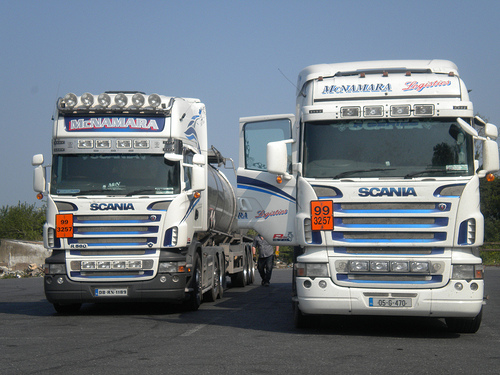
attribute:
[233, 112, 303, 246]
truck door — OPEN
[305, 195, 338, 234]
sign — red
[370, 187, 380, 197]
letter — blue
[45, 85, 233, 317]
truck —  left 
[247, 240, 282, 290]
man — walking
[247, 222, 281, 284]
man — walking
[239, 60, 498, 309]
truck — large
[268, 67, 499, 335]
truck — large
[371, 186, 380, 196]
letter — blue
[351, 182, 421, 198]
letter — blue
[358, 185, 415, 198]
label — blue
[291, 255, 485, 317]
bumper — white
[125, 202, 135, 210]
letter — blue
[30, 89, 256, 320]
truck — large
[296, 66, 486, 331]
truck — open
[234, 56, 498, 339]
truck — large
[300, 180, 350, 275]
sign —  orange 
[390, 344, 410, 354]
spot — small, black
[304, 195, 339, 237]
sign — small, orange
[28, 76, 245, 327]
truck — large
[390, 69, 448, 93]
writing — red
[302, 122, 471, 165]
window — windshield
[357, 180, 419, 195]
lettering — blue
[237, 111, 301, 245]
door — open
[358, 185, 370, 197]
letter — blue